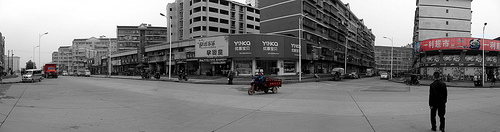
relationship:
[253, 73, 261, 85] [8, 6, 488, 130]
man on street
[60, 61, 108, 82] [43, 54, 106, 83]
line of cars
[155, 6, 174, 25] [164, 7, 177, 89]
light suspended on pole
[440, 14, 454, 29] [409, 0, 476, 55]
window on building